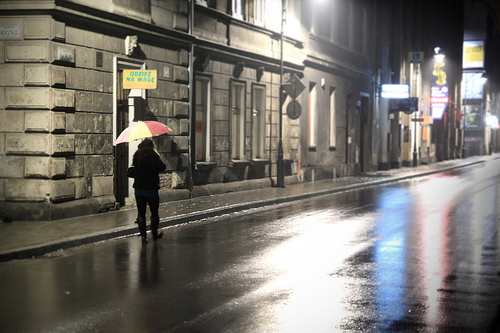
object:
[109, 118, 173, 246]
woman umbrella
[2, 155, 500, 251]
sidewalk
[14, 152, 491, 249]
sidewalk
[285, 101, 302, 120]
sign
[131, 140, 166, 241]
woman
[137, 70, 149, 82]
writing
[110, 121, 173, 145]
umbrella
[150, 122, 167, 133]
part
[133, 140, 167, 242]
person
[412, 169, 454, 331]
reflection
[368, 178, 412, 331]
reflection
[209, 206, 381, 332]
reflection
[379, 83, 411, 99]
light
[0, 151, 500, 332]
pavement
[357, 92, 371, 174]
door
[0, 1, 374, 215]
building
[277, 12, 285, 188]
pole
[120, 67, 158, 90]
sign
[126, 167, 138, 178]
handbag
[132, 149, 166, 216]
clothing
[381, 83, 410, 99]
sign